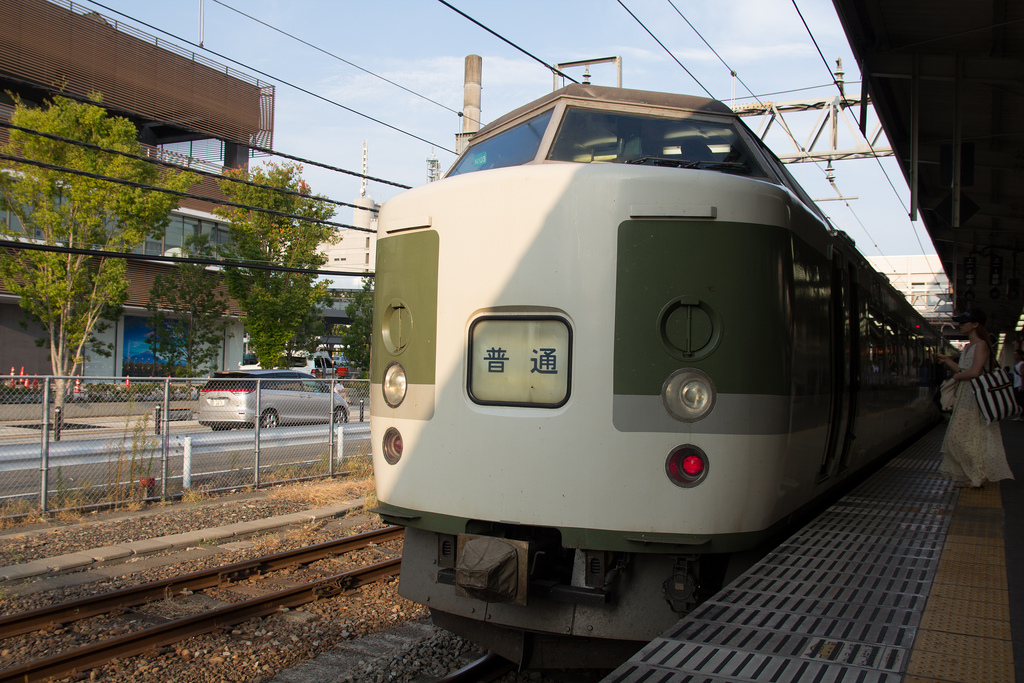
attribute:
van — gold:
[197, 361, 355, 435]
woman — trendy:
[932, 310, 1015, 485]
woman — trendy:
[932, 305, 1021, 493]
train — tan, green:
[364, 80, 969, 679]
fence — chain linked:
[3, 372, 373, 526]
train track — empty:
[1, 525, 406, 679]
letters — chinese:
[421, 303, 594, 403]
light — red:
[598, 407, 778, 518]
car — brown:
[181, 348, 369, 435]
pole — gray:
[161, 415, 220, 524]